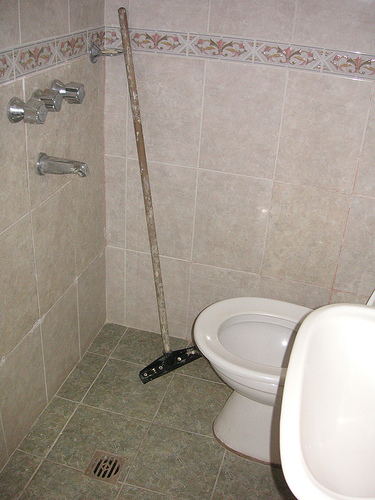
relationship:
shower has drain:
[8, 79, 125, 484] [84, 449, 126, 483]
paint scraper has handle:
[118, 8, 201, 384] [119, 6, 176, 352]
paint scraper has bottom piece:
[118, 8, 201, 384] [138, 347, 203, 383]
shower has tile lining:
[8, 79, 125, 484] [1, 27, 374, 85]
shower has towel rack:
[8, 79, 125, 484] [88, 44, 121, 63]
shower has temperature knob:
[8, 79, 125, 484] [8, 98, 48, 123]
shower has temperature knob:
[8, 79, 125, 484] [53, 80, 86, 103]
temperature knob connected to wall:
[8, 98, 48, 123] [1, 0, 104, 469]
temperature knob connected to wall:
[53, 80, 86, 103] [1, 0, 104, 469]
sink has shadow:
[280, 300, 373, 498] [271, 303, 326, 500]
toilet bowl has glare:
[192, 299, 315, 404] [281, 338, 287, 346]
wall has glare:
[102, 3, 372, 343] [258, 208, 268, 214]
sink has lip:
[280, 300, 373, 498] [277, 301, 372, 499]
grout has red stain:
[45, 457, 122, 485] [48, 460, 81, 472]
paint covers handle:
[119, 10, 169, 355] [119, 6, 176, 352]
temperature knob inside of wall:
[8, 98, 48, 123] [1, 0, 104, 469]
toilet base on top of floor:
[212, 388, 285, 468] [12, 321, 296, 500]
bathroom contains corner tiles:
[1, 0, 373, 498] [70, 0, 126, 358]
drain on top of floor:
[84, 449, 126, 483] [12, 321, 296, 500]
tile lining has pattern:
[1, 27, 374, 85] [173, 32, 233, 60]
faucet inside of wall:
[38, 154, 88, 175] [1, 0, 104, 469]